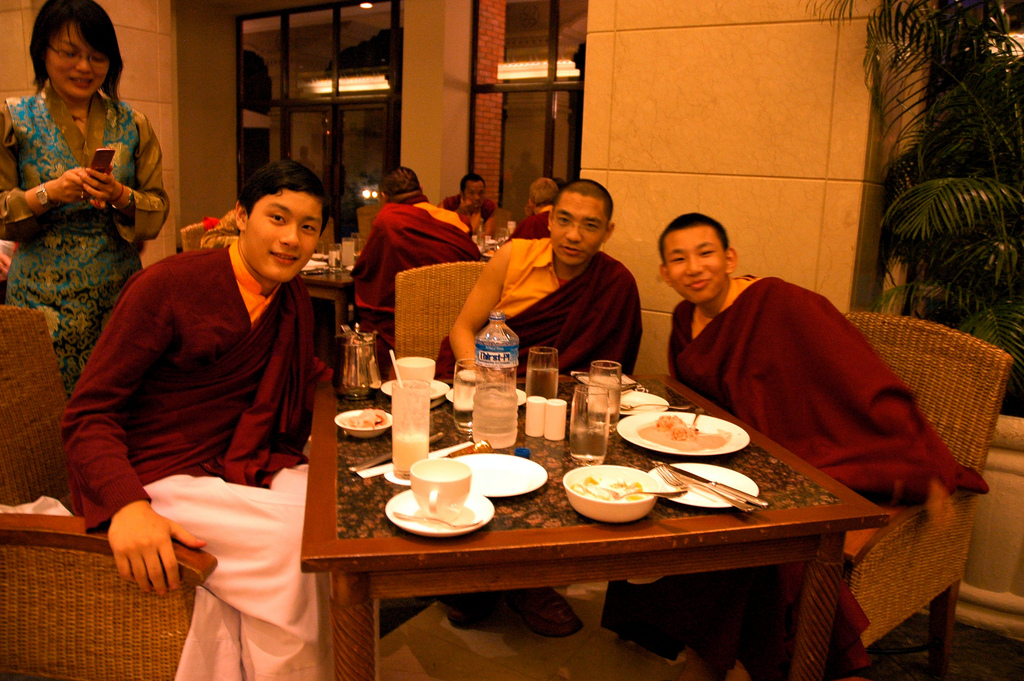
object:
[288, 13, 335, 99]
glass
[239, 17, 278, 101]
glass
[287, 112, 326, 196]
glass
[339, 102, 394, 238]
glass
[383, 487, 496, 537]
dish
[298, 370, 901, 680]
table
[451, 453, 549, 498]
dish